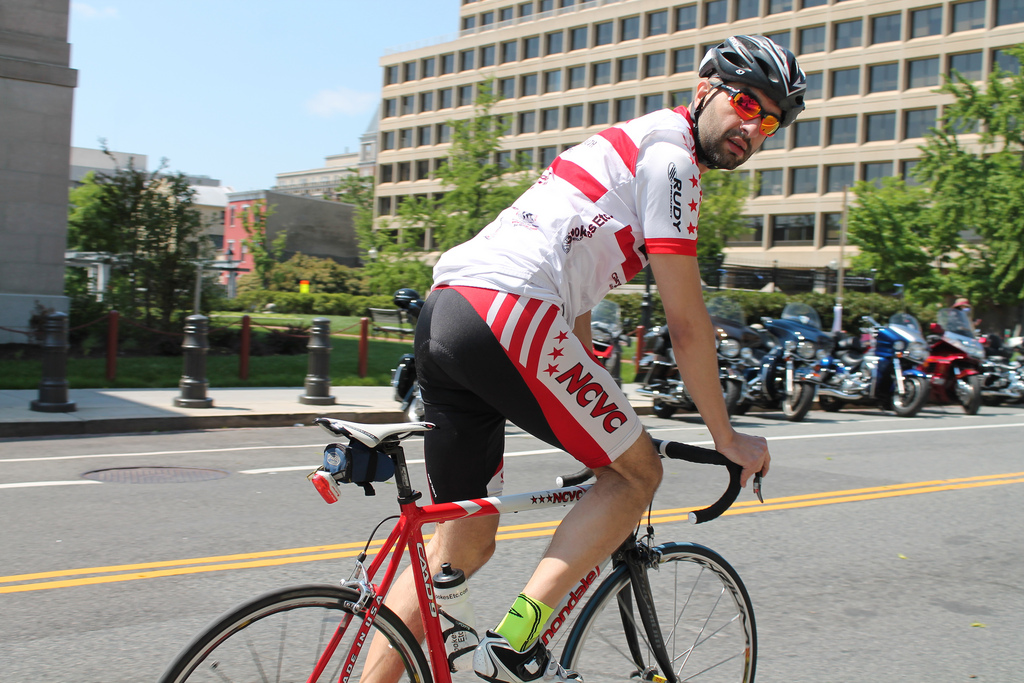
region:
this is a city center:
[58, 37, 950, 648]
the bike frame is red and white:
[351, 473, 573, 671]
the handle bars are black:
[617, 423, 792, 522]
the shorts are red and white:
[336, 236, 839, 601]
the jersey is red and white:
[479, 66, 821, 332]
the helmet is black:
[658, 10, 859, 162]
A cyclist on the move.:
[162, 38, 808, 677]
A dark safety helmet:
[700, 17, 808, 128]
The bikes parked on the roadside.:
[398, 295, 1022, 416]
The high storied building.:
[373, 0, 1022, 318]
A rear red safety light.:
[309, 469, 339, 504]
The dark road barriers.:
[40, 313, 338, 408]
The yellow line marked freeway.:
[0, 409, 1023, 679]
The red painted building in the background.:
[220, 187, 353, 293]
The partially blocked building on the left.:
[0, 0, 89, 351]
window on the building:
[784, 205, 817, 247]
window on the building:
[832, 214, 880, 259]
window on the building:
[728, 209, 766, 245]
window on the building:
[380, 225, 394, 257]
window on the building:
[378, 200, 399, 208]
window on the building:
[374, 170, 387, 181]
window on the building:
[419, 164, 449, 174]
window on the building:
[419, 117, 457, 149]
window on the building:
[814, 117, 834, 138]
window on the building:
[506, 149, 539, 173]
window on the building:
[740, 208, 814, 246]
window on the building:
[855, 121, 913, 140]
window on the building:
[386, 117, 437, 141]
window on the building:
[225, 206, 252, 226]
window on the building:
[501, 117, 552, 160]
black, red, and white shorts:
[419, 275, 651, 501]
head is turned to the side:
[688, 26, 815, 185]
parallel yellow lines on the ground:
[4, 427, 1023, 602]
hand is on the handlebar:
[704, 418, 787, 499]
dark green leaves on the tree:
[835, 42, 1023, 321]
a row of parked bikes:
[656, 289, 1023, 408]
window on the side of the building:
[820, 105, 862, 145]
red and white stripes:
[486, 286, 569, 378]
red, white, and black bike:
[143, 414, 791, 680]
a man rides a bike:
[117, 19, 828, 680]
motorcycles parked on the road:
[710, 280, 1022, 441]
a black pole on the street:
[19, 300, 87, 426]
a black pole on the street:
[169, 305, 221, 420]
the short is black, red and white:
[398, 282, 653, 504]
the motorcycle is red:
[913, 319, 1000, 420]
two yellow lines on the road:
[811, 444, 1019, 520]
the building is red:
[208, 182, 286, 291]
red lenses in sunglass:
[695, 78, 779, 139]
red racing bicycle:
[142, 403, 778, 680]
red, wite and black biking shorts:
[410, 286, 642, 490]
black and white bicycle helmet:
[692, 21, 809, 116]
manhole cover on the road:
[81, 450, 237, 489]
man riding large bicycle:
[355, 30, 839, 680]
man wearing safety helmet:
[692, 27, 811, 127]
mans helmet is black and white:
[699, 23, 814, 145]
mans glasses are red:
[706, 77, 780, 139]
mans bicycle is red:
[123, 378, 765, 680]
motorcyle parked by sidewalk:
[638, 279, 831, 429]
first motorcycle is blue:
[636, 295, 823, 429]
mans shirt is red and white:
[392, 102, 712, 340]